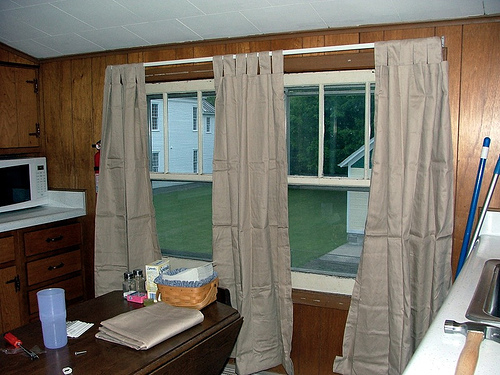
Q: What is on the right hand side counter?
A: Hammer.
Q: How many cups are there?
A: 1.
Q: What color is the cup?
A: Blue.